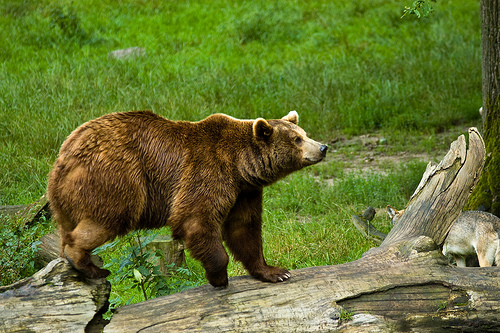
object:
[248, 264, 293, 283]
foot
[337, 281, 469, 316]
hole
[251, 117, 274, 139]
ear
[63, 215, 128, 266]
leg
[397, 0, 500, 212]
tree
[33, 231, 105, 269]
stump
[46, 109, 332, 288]
bear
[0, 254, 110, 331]
trunk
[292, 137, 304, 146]
eye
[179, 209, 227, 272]
right leg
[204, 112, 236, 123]
hump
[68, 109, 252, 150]
back